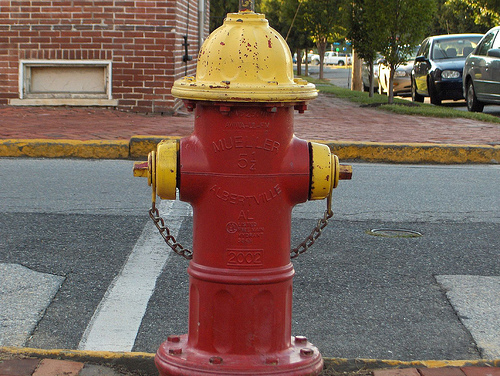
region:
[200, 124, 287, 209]
MUELLER 51/2 ALBERVILLE written on Hydrant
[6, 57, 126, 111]
white basement window casement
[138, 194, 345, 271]
chain hanging from fire hydrant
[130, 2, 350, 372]
red and yellow fire hydrant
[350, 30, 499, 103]
cars parked along the street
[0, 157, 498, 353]
a concrete city street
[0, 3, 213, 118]
building made of red bricks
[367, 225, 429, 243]
man hole cover in the street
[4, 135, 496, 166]
a yellow curb on the street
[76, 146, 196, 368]
white line painted on street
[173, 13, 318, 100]
yellow top on the hydrant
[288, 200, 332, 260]
chain hanging from the hydrant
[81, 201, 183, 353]
white paint on the street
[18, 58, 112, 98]
a closed off window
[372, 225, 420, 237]
a small man hole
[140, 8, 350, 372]
a red and yellow fire hydrant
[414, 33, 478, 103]
a black car parked on the street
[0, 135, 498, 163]
a yellow street curb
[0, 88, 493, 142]
red brick sidewalk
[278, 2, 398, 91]
a row of trees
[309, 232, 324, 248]
Chain on red and yellow fire hyrdrant.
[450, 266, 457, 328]
Chain on red and yellow fire hyrdrant.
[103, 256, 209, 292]
Chain on red and yellow fire hyrdrant.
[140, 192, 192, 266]
chain on a fire hydrant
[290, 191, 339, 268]
chain on a fire hydrant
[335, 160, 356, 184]
bolt on a fire hydrant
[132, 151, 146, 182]
bolt on a fire hydrant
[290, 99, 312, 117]
bolt on a fire hydrant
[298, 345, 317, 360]
bolt on a fire hydrant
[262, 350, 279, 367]
bolt on a fire hydrant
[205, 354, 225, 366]
bolt on a fire hydrant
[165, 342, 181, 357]
bolt on a fire hydrant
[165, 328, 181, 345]
bolt on a fire hydrant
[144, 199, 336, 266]
Chains on a fire hydrant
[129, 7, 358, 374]
A red and yellow fire hydrant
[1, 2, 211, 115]
Brown bricks on a building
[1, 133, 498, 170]
The curb is yellow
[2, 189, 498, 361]
White markings on the road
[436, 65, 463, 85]
A headlight on a car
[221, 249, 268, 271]
"2002" written on a fire hydrant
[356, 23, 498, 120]
Cars parked on the side of a road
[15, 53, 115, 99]
A window on a building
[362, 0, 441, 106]
Green leaves on a small tree